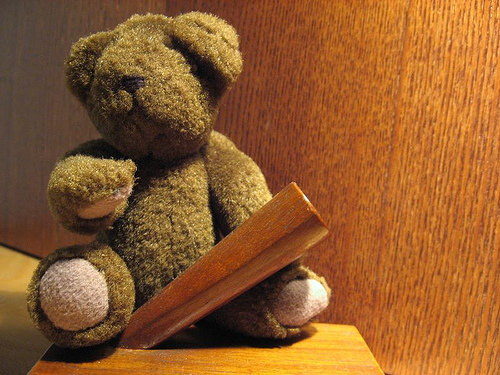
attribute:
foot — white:
[25, 246, 134, 349]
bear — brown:
[26, 13, 334, 351]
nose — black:
[116, 74, 147, 93]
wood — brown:
[119, 177, 333, 352]